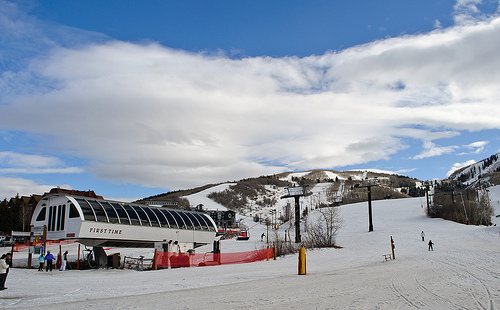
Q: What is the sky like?
A: Cloudy.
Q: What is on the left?
A: Transport system.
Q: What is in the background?
A: Mountains.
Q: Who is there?
A: Skiers.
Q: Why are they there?
A: To ski.